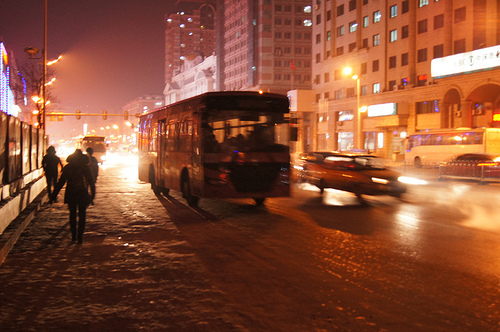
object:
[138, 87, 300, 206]
bus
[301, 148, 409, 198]
car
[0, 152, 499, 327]
road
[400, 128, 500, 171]
bus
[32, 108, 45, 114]
lights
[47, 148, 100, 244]
people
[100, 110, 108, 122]
traffic lights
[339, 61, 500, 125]
several lights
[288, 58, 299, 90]
flag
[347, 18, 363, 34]
windows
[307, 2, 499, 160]
building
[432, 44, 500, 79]
sign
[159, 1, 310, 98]
buildings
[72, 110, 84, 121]
stoplight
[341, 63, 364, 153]
streetlight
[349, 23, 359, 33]
lights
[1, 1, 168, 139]
sky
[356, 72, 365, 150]
pole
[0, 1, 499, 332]
scene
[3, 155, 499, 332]
snow